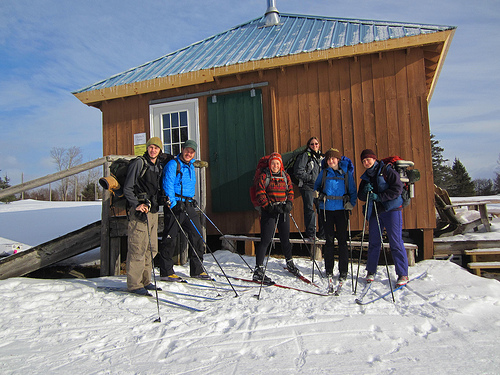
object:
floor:
[245, 308, 314, 357]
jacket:
[123, 153, 167, 212]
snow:
[0, 196, 499, 374]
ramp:
[0, 220, 104, 281]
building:
[72, 0, 457, 276]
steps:
[433, 233, 498, 247]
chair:
[433, 184, 492, 236]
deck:
[433, 235, 475, 259]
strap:
[318, 196, 348, 202]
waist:
[323, 195, 346, 202]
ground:
[0, 194, 499, 373]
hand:
[275, 206, 285, 217]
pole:
[257, 210, 282, 300]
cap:
[359, 148, 374, 162]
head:
[360, 148, 376, 169]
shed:
[315, 58, 332, 154]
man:
[123, 136, 169, 296]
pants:
[125, 202, 160, 297]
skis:
[277, 261, 327, 289]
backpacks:
[280, 145, 311, 184]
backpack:
[249, 156, 270, 214]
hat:
[267, 151, 284, 162]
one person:
[293, 136, 325, 242]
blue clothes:
[358, 161, 409, 276]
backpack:
[379, 155, 421, 205]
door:
[149, 98, 202, 214]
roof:
[71, 0, 457, 104]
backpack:
[106, 156, 133, 207]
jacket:
[256, 169, 294, 207]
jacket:
[294, 148, 323, 188]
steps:
[466, 247, 499, 256]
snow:
[470, 246, 486, 253]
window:
[178, 109, 190, 127]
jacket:
[163, 154, 198, 208]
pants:
[159, 201, 207, 278]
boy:
[252, 153, 300, 285]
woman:
[293, 136, 325, 243]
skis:
[354, 269, 429, 304]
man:
[160, 138, 212, 279]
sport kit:
[313, 146, 358, 282]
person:
[314, 147, 357, 280]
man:
[357, 148, 409, 286]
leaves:
[453, 168, 470, 186]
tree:
[450, 156, 476, 197]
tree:
[82, 174, 99, 199]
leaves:
[87, 182, 96, 195]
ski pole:
[144, 213, 162, 322]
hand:
[135, 203, 152, 215]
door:
[206, 86, 268, 214]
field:
[0, 195, 498, 374]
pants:
[364, 197, 409, 276]